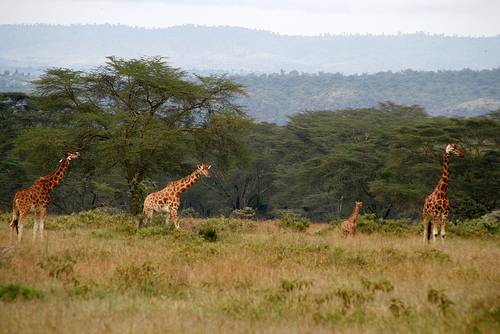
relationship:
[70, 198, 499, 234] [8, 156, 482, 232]
bushes on background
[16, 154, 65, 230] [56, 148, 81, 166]
giraffe has a head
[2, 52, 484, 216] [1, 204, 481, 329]
trees beyond field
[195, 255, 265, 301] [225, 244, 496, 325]
grass on field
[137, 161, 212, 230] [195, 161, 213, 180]
giraffe has head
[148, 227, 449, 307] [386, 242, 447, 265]
grasslands has plants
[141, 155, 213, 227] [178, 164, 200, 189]
giraffe has neck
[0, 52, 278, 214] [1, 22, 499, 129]
trees on background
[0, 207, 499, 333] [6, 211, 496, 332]
grass on ground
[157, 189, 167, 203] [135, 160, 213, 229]
spots on giraffe